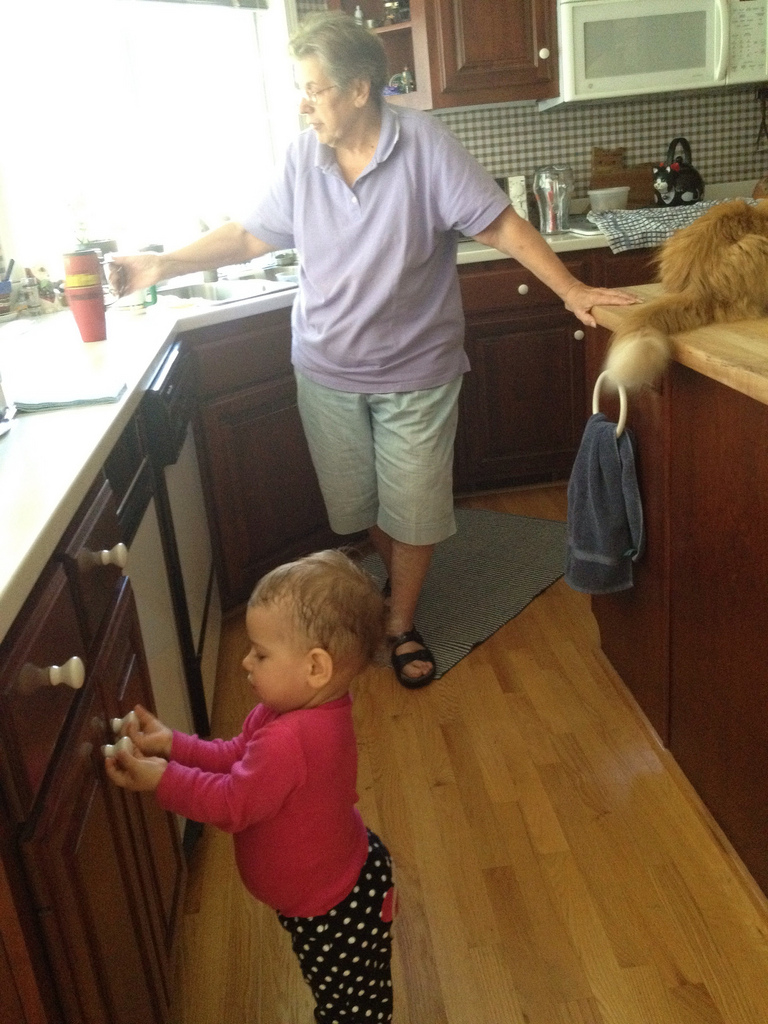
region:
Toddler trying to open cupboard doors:
[114, 549, 416, 1020]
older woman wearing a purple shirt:
[113, 22, 642, 684]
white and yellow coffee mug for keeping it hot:
[63, 252, 135, 340]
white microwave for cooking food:
[536, 0, 766, 115]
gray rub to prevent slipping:
[320, 505, 595, 687]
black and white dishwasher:
[139, 336, 237, 728]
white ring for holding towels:
[589, 362, 631, 442]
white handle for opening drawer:
[97, 541, 128, 571]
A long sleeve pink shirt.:
[154, 686, 371, 921]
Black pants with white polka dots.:
[276, 827, 394, 1021]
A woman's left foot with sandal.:
[380, 611, 438, 692]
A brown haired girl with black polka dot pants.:
[102, 547, 399, 1022]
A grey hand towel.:
[568, 412, 644, 593]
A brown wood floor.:
[184, 488, 766, 1022]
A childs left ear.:
[307, 648, 334, 689]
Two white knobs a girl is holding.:
[102, 710, 138, 757]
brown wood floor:
[170, 473, 765, 1021]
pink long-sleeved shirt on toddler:
[149, 688, 393, 930]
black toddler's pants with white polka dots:
[262, 824, 419, 1021]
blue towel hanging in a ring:
[555, 397, 651, 608]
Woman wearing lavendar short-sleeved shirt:
[95, 12, 636, 696]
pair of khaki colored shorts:
[279, 336, 480, 558]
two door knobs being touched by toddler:
[92, 703, 149, 769]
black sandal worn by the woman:
[380, 620, 442, 693]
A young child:
[109, 550, 449, 1016]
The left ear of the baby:
[295, 642, 341, 699]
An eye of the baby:
[240, 638, 283, 667]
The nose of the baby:
[234, 652, 262, 670]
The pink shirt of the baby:
[158, 710, 389, 908]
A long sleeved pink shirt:
[165, 711, 389, 903]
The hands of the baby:
[99, 701, 179, 790]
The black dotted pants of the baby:
[240, 846, 433, 1021]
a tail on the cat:
[605, 253, 727, 380]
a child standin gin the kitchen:
[201, 563, 552, 1017]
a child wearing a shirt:
[186, 563, 462, 925]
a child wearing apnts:
[142, 668, 409, 1003]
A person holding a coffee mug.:
[59, 37, 582, 616]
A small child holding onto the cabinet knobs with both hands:
[132, 490, 432, 992]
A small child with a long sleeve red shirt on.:
[121, 534, 431, 1016]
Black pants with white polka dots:
[266, 837, 406, 1021]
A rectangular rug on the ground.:
[286, 491, 591, 688]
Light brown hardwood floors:
[210, 487, 762, 1002]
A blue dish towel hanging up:
[562, 361, 648, 618]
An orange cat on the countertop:
[587, 171, 765, 416]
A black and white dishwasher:
[129, 340, 240, 725]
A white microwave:
[545, 1, 765, 108]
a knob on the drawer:
[79, 526, 130, 573]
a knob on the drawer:
[17, 606, 102, 712]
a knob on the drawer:
[94, 734, 128, 781]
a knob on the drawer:
[103, 697, 149, 746]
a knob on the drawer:
[569, 315, 593, 331]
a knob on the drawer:
[484, 253, 536, 304]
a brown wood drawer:
[34, 620, 95, 718]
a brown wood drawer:
[78, 509, 122, 583]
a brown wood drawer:
[437, 249, 618, 314]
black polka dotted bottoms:
[232, 814, 439, 1022]